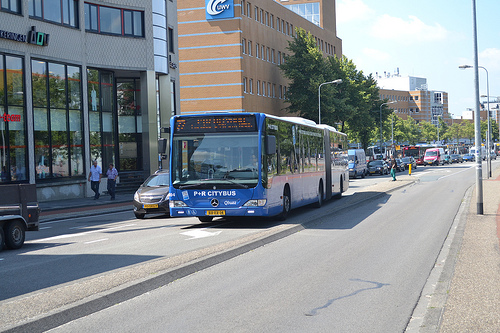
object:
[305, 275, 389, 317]
patch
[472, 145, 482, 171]
sticker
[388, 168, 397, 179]
pants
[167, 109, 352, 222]
bus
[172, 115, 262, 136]
destination sign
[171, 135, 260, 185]
wind shield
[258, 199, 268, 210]
head light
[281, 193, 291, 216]
tire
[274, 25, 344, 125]
tree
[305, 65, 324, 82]
leaves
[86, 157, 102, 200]
man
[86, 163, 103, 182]
shirt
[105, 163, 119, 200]
man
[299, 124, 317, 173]
windows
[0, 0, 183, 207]
building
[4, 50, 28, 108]
windows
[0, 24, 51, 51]
name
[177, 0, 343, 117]
building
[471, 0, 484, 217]
poles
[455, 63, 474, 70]
streetlight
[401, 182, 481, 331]
sidewalk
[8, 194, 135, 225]
pavement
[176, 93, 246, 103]
blue line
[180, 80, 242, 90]
blue line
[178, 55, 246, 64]
blue line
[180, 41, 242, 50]
blue line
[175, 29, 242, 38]
blue line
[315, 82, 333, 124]
light post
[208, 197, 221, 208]
brand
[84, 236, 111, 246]
white line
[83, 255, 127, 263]
asphalt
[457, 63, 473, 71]
light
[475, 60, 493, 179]
pole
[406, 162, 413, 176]
pole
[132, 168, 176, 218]
car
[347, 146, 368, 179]
van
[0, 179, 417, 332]
median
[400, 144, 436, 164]
bus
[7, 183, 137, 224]
sidewalk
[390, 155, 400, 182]
man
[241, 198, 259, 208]
headlight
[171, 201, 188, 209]
headlight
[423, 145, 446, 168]
van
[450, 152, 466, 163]
car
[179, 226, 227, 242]
arrow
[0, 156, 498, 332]
road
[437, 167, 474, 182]
line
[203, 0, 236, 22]
sign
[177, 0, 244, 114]
wall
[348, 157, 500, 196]
intersection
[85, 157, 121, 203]
couple